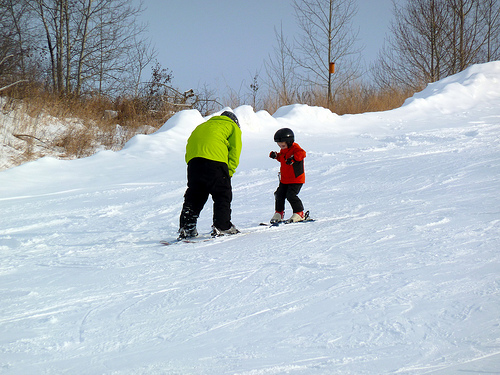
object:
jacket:
[273, 142, 306, 184]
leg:
[213, 188, 232, 229]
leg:
[288, 187, 305, 214]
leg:
[273, 183, 288, 213]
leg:
[180, 182, 208, 222]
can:
[330, 61, 335, 73]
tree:
[273, 0, 379, 110]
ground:
[0, 121, 499, 375]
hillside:
[0, 58, 500, 368]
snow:
[344, 138, 380, 165]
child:
[268, 127, 307, 223]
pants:
[273, 182, 303, 214]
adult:
[174, 110, 242, 239]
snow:
[329, 171, 478, 324]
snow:
[0, 206, 121, 373]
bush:
[53, 125, 99, 160]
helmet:
[273, 128, 294, 148]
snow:
[215, 272, 277, 334]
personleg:
[285, 193, 305, 216]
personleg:
[273, 188, 283, 215]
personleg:
[208, 179, 232, 225]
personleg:
[180, 182, 209, 226]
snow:
[13, 158, 79, 228]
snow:
[335, 322, 349, 343]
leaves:
[409, 0, 432, 22]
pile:
[401, 58, 500, 113]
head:
[274, 127, 295, 149]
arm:
[290, 149, 305, 164]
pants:
[179, 157, 233, 233]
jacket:
[184, 114, 242, 177]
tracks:
[0, 90, 500, 370]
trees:
[0, 0, 216, 115]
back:
[183, 116, 234, 162]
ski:
[260, 217, 291, 225]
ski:
[270, 210, 314, 224]